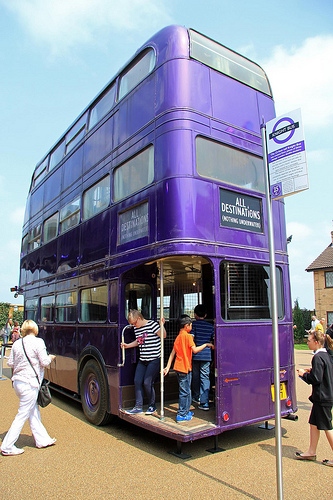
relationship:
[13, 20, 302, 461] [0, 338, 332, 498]
bus on road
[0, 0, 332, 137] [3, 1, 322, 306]
clouds in sky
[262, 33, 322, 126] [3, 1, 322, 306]
clouds in sky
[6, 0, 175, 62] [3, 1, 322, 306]
cloud in sky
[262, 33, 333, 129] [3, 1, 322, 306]
clouds in sky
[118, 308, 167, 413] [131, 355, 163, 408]
person wearing pants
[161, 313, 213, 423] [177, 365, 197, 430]
person wearing pants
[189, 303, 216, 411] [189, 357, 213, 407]
person wearing pants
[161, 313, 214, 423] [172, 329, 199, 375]
boy wearing shirt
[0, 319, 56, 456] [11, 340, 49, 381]
lady wearing shirt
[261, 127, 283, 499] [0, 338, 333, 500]
pole near road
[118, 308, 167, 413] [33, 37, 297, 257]
person getting off bus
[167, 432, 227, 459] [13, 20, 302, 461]
bars under bus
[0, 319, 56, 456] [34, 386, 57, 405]
lady with a messenger bag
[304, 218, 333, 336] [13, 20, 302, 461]
building behind bus